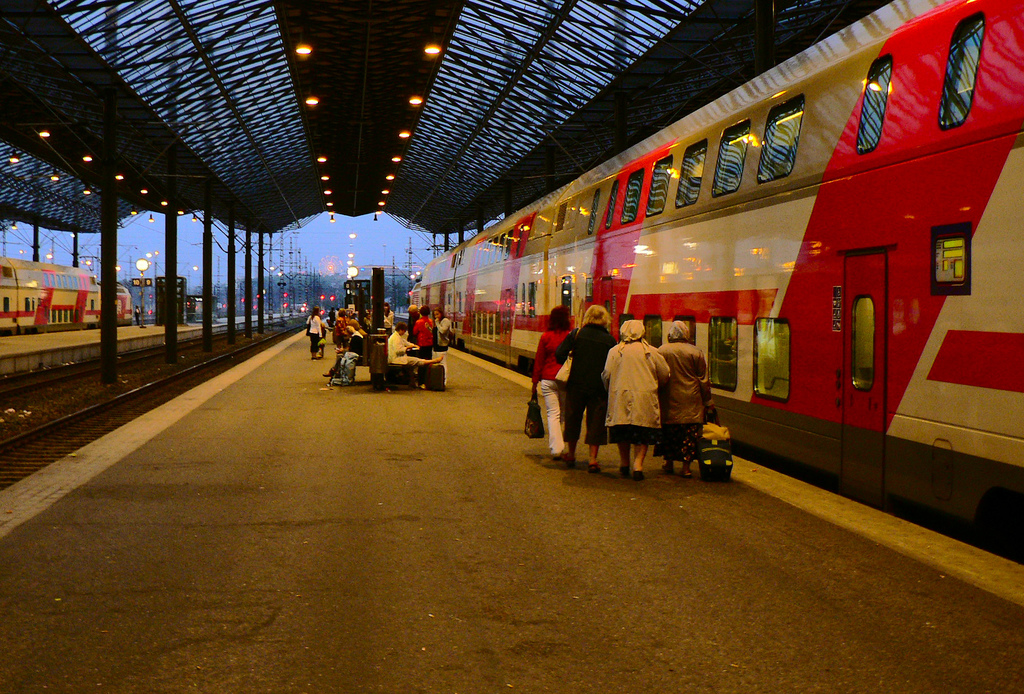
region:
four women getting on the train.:
[505, 315, 753, 524]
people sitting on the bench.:
[290, 276, 472, 422]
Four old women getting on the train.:
[494, 280, 785, 505]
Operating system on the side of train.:
[925, 215, 974, 296]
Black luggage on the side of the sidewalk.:
[691, 404, 734, 480]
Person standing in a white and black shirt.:
[305, 303, 337, 367]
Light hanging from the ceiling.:
[292, 86, 325, 116]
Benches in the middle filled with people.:
[356, 309, 421, 382]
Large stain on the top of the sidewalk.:
[79, 473, 250, 496]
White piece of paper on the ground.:
[410, 639, 427, 650]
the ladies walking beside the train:
[512, 308, 719, 483]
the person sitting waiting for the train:
[377, 315, 441, 395]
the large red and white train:
[409, 94, 998, 491]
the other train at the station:
[13, 246, 137, 348]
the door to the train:
[831, 232, 904, 501]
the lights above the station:
[266, 34, 426, 234]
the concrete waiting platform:
[45, 303, 814, 676]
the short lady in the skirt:
[602, 319, 660, 481]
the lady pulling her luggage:
[654, 327, 741, 483]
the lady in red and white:
[523, 327, 571, 467]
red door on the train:
[834, 246, 899, 453]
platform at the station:
[19, 309, 1022, 692]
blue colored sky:
[0, 193, 478, 292]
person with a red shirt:
[411, 303, 440, 358]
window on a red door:
[847, 290, 876, 405]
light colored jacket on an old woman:
[597, 331, 673, 443]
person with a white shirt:
[384, 322, 441, 390]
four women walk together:
[521, 297, 721, 488]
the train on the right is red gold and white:
[406, 17, 1020, 564]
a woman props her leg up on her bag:
[382, 318, 452, 388]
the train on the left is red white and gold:
[0, 250, 137, 340]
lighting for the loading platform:
[283, 23, 445, 227]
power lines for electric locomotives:
[0, 67, 317, 397]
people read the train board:
[302, 296, 366, 363]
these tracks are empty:
[0, 303, 325, 497]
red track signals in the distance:
[227, 281, 352, 321]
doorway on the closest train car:
[828, 243, 893, 513]